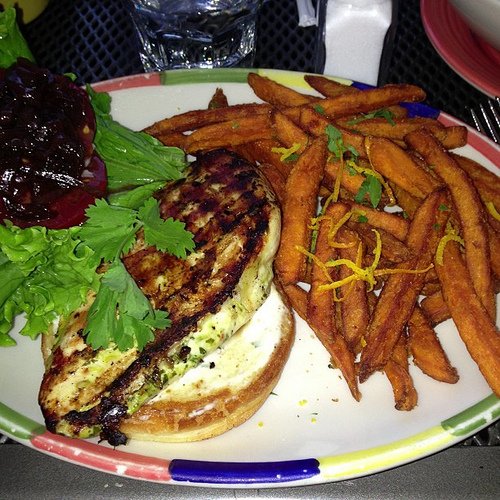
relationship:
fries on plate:
[346, 193, 426, 263] [5, 66, 496, 495]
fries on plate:
[247, 83, 494, 402] [5, 66, 496, 495]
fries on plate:
[137, 72, 499, 412] [280, 404, 373, 464]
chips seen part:
[327, 210, 383, 376] [345, 234, 358, 262]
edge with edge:
[418, 0, 500, 100] [418, 1, 498, 103]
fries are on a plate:
[137, 72, 499, 412] [5, 66, 496, 495]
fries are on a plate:
[312, 255, 489, 380] [272, 408, 355, 454]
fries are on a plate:
[247, 83, 494, 402] [5, 66, 496, 495]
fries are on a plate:
[199, 55, 455, 369] [42, 45, 479, 489]